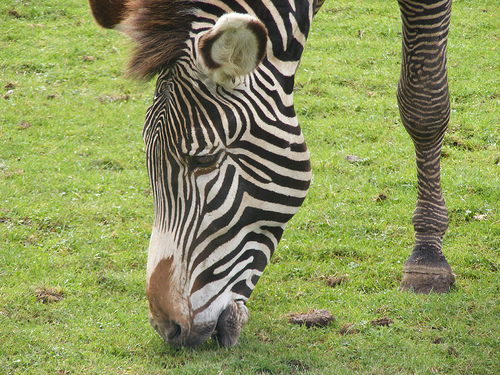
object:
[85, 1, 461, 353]
zebra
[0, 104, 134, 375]
grass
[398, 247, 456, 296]
hoof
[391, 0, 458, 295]
leg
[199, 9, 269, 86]
ear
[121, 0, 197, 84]
mane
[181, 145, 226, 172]
eye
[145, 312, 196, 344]
nose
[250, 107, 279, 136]
fur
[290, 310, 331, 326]
dirt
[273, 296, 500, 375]
grass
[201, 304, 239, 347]
mouth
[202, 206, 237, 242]
stripes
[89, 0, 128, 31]
ears